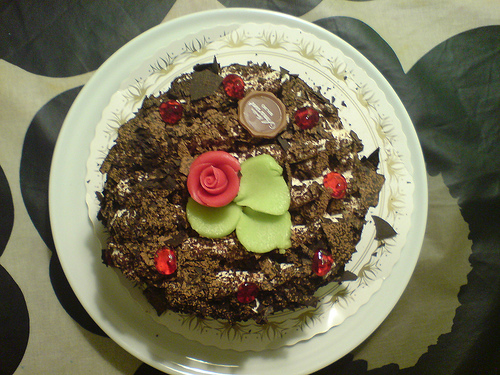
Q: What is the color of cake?
A: Brown.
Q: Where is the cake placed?
A: On plate.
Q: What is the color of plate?
A: White.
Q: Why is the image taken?
A: Remembrance.